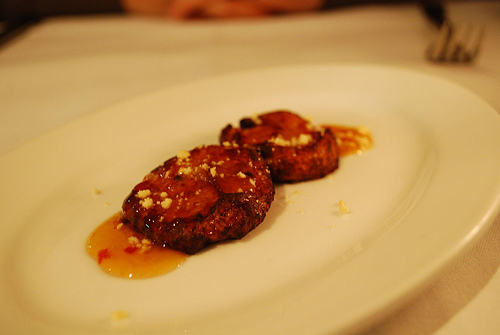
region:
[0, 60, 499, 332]
Dinner plate with sauteed steak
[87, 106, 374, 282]
Sauteed meat on white plate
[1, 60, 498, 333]
Culinary steak with sauce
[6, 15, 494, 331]
Steak on a white plate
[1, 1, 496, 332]
Dinner plate containing seasoned steak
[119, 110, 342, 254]
Two small plated steaks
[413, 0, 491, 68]
Stainless steel fork with black handle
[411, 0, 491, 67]
Dinner fork on the table.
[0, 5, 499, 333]
Meat dish on the table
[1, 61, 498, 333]
Sauteed steak served for dinner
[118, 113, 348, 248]
a couple of donuts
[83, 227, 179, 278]
a yellow silvery substance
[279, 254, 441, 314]
a brown mellanine plate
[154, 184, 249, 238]
a brown colored donut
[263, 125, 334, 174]
small piece of donut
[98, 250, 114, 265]
a red yucky patch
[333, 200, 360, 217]
a small yellow piece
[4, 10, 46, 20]
a black dark surface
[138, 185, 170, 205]
yellow pieces of donut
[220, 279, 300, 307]
clean part of plate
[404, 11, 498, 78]
a blurry fork in the background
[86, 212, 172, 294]
a viscous sauce with chili flakes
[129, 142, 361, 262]
two fried patties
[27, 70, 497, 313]
a large white plate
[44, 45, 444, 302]
a well presented appetizer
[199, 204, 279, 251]
slightly charred edges of the food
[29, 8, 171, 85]
a crisp white table clothe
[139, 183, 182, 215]
a crumbled garnish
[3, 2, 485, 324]
a focused picture of an appetizer in a restaurant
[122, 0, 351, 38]
the blurry folded hands of the other diner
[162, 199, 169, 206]
white garnish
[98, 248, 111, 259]
speck of red garnish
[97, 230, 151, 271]
brown sauce containing red and white garnish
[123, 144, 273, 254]
piece of meat topped with a brown sauce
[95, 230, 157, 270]
brown sauce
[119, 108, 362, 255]
two well cooked pieces of meat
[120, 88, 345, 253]
brown meat on a white plate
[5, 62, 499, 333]
white containing small pieces of meat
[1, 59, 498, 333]
a plate of a small amount of food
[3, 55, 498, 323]
a white plate of two pieces of meat topped with sauce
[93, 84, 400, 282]
the plate with cooked food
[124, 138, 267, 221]
seasoning on the meat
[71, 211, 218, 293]
a drizzle sauce falling from the meat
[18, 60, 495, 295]
and oval-shaped white plate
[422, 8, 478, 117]
a metal fork in the background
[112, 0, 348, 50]
a napkin in the background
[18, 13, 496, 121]
a white table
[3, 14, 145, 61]
the corner of the white table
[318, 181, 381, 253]
food crumbs on the plate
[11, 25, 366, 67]
shadow running along the table